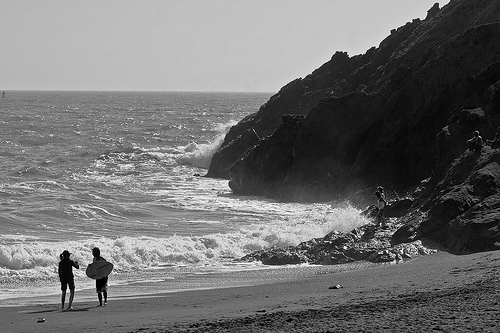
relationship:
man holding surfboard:
[88, 246, 113, 308] [83, 259, 133, 286]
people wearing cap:
[56, 249, 79, 312] [62, 250, 72, 255]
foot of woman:
[55, 301, 72, 316] [46, 234, 90, 320]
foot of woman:
[66, 306, 73, 311] [46, 233, 86, 313]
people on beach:
[56, 249, 79, 312] [6, 236, 497, 328]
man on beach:
[88, 246, 113, 308] [0, 257, 496, 330]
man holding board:
[84, 241, 134, 311] [82, 256, 122, 283]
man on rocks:
[359, 171, 402, 230] [356, 166, 467, 254]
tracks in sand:
[182, 269, 494, 330] [2, 250, 497, 330]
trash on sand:
[328, 283, 344, 289] [9, 234, 498, 330]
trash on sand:
[31, 317, 49, 330] [9, 234, 498, 330]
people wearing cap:
[56, 249, 79, 312] [58, 245, 75, 262]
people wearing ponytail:
[56, 249, 79, 312] [59, 253, 63, 261]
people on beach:
[53, 236, 134, 309] [6, 265, 498, 331]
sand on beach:
[14, 265, 490, 325] [6, 236, 497, 328]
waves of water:
[0, 194, 370, 281] [2, 87, 372, 304]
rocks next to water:
[267, 171, 489, 290] [2, 87, 372, 304]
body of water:
[87, 257, 111, 308] [2, 87, 372, 304]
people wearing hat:
[56, 249, 79, 312] [55, 244, 75, 261]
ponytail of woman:
[54, 250, 69, 264] [46, 240, 88, 320]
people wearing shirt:
[56, 249, 79, 312] [51, 258, 81, 276]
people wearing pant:
[56, 249, 79, 312] [56, 277, 77, 290]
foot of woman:
[64, 305, 76, 310] [58, 250, 81, 313]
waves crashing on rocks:
[151, 118, 226, 177] [212, 0, 482, 209]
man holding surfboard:
[88, 246, 113, 308] [84, 263, 116, 277]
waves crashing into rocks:
[181, 135, 369, 250] [210, 10, 484, 278]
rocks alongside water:
[210, 10, 484, 278] [2, 91, 395, 293]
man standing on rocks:
[372, 191, 389, 228] [242, 183, 427, 269]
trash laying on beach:
[326, 283, 340, 290] [14, 237, 484, 320]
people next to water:
[56, 249, 79, 312] [2, 87, 372, 304]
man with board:
[88, 246, 113, 308] [85, 260, 115, 277]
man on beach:
[88, 246, 113, 308] [9, 225, 486, 319]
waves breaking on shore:
[0, 194, 370, 281] [18, 226, 478, 323]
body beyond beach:
[5, 91, 365, 270] [9, 225, 486, 319]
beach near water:
[7, 261, 481, 322] [13, 91, 348, 279]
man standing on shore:
[372, 191, 389, 228] [215, 120, 486, 270]